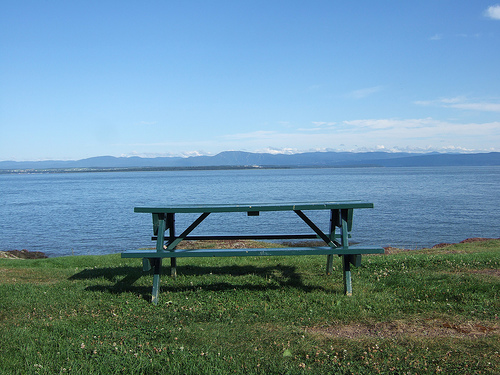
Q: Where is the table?
A: On the grass.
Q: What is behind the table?
A: Water.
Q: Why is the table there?
A: To sit and eat.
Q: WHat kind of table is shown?
A: Picnic table.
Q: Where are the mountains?
A: Across the water.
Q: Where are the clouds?
A: In the sky.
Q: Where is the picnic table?
A: In the grass.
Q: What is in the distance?
A: Mountains.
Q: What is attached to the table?
A: Seats.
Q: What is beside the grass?
A: Water.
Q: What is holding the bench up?
A: Feet.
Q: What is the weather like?
A: Sunny.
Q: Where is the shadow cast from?
A: Bench.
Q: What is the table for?
A: To eat at.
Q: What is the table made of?
A: Wood.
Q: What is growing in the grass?
A: Weeds.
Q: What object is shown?
A: Picnic table.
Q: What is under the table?
A: Grass.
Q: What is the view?
A: Snow capped mountains.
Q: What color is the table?
A: Blue.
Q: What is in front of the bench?
A: A body of water.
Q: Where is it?
A: At a rest stop.